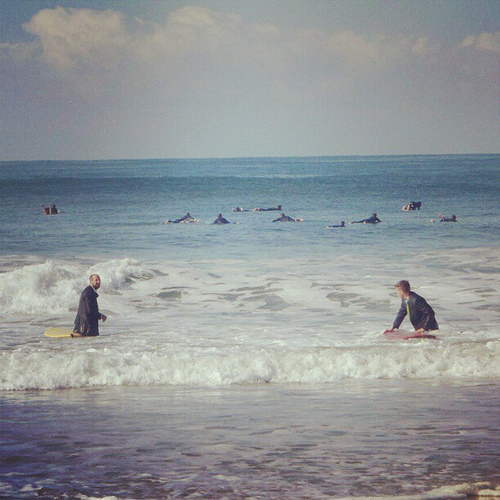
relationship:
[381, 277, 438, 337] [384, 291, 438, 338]
person wearing suit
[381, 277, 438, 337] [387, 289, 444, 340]
person wearing suit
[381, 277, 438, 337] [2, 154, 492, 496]
person standing in water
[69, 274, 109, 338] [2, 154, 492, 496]
person standing in water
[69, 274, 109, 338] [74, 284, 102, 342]
person wearing suit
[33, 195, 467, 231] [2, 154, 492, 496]
people standing in water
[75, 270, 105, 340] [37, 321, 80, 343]
man standing in board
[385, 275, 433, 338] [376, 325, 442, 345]
man standing in board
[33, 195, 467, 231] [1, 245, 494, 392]
people beyond waves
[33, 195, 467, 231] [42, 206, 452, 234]
people are standing in boards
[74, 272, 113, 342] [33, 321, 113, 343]
surfer on board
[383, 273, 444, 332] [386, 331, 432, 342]
surfer with board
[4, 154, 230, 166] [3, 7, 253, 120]
line between sky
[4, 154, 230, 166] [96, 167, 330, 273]
line between ocean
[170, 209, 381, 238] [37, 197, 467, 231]
group of surfers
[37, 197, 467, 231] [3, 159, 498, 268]
surfers in back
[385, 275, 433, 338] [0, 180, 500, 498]
man in water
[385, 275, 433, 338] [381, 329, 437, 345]
man with a surfboard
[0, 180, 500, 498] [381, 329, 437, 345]
water with a surfboard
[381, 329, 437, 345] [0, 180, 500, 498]
surfboard in water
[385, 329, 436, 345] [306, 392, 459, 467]
surfboard in water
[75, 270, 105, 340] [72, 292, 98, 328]
man in a coat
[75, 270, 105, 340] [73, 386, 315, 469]
man in water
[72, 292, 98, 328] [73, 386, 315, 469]
coat in water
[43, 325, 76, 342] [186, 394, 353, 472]
surfboard in water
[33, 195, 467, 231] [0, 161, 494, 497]
people floating in ocean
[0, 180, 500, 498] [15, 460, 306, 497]
water rolling into shore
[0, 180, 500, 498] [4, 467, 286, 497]
water sliding onto a beach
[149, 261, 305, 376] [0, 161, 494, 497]
water in ocean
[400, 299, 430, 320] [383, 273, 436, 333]
jacket on a man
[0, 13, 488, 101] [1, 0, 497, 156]
clouds in sky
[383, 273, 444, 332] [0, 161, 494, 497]
surfer in ocean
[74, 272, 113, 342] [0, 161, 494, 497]
surfer in ocean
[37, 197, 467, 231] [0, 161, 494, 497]
surfers in ocean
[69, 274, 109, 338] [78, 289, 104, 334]
person wearing suit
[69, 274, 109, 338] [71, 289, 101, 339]
person wearing suit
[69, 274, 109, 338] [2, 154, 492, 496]
person in water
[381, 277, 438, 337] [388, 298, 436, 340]
person wearing suit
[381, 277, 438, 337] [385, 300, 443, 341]
person wearing suit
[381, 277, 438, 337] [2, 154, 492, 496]
person in water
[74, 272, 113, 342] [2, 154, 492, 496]
surfer in water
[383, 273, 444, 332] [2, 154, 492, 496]
surfer in water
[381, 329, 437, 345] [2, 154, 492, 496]
surfboard in water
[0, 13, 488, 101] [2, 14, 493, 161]
clouds in sky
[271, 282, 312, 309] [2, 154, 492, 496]
bubbles in water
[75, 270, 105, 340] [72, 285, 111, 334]
man in suit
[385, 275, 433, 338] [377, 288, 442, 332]
man in suit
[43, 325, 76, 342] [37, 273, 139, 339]
surfboard held by man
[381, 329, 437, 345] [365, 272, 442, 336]
surfboard held by man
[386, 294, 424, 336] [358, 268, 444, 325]
tie on man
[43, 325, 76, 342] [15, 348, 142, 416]
surfboard in water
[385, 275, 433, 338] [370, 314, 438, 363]
man holding surfboard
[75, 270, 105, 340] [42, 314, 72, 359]
man holding surfboard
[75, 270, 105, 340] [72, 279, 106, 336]
man in jacket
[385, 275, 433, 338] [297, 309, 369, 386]
man in ocean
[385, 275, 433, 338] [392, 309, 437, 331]
man wearing suit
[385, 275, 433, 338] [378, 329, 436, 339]
man holding surf board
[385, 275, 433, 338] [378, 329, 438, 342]
man has surfboard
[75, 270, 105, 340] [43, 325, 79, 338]
man has surfboard